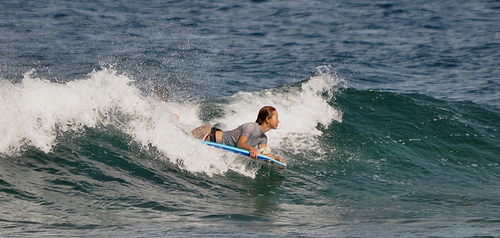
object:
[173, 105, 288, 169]
man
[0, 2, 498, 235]
water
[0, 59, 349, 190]
wave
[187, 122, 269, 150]
suit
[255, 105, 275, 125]
hair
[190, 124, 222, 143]
pants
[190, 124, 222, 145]
bottom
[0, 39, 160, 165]
spray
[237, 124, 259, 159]
hand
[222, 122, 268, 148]
shirt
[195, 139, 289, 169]
board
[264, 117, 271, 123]
ear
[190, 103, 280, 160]
woman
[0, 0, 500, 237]
ocean